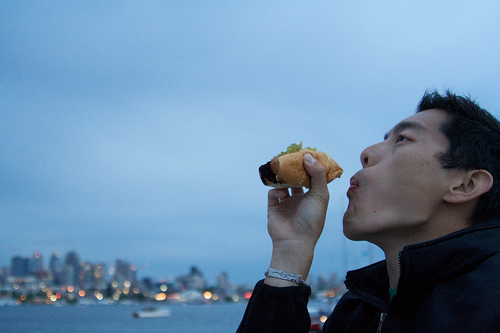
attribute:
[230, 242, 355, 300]
wrist — man's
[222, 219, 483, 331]
jacket — dark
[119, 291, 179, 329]
boat — white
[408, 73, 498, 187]
hair — black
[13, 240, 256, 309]
light — city, in background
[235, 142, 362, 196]
dog — hot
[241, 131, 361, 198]
dog — hot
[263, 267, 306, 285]
bracelet — Silver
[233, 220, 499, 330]
sweatshirt — black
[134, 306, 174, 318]
boat — White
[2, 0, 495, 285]
sky — light blue, overcast, white, cloudy, blue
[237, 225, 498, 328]
jacket — black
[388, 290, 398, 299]
shirt — green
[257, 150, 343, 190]
bun — burned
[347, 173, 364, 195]
mouth — closed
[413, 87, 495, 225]
hair — black, short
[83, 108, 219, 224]
clouds — white